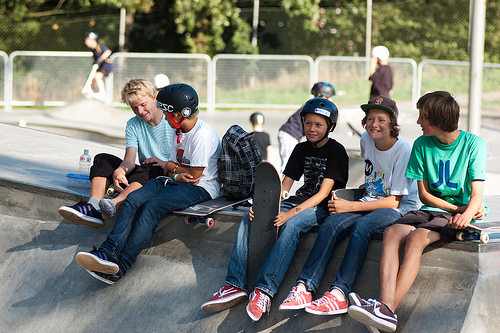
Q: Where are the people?
A: Skate park.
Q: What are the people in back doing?
A: Skating.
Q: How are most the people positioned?
A: Sitting.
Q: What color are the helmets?
A: Black.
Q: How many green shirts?
A: One.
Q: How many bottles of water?
A: One.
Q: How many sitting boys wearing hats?
A: One.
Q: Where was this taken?
A: Skate park.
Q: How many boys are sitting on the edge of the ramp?
A: 5.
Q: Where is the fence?
A: Around the skate park.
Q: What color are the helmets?
A: Black.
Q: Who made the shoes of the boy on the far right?
A: Nike.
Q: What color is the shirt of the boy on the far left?
A: Blue.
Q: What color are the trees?
A: Green.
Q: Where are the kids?
A: At a skatepark.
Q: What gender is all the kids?
A: Male.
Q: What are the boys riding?
A: Skateboards.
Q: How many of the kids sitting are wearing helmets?
A: 2.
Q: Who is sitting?
A: The boys.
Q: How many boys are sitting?
A: 5.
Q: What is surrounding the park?
A: A fence.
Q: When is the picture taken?
A: Daytime.